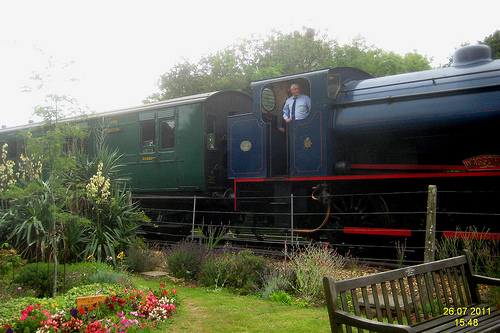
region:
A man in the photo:
[282, 74, 307, 121]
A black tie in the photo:
[290, 98, 300, 122]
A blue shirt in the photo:
[278, 94, 310, 121]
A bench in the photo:
[321, 264, 463, 323]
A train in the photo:
[336, 84, 496, 170]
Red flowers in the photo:
[21, 302, 38, 321]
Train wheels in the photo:
[316, 191, 404, 234]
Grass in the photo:
[203, 297, 267, 328]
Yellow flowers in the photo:
[87, 162, 112, 197]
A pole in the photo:
[424, 189, 440, 264]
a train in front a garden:
[5, 43, 497, 260]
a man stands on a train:
[221, 48, 346, 178]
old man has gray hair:
[274, 73, 315, 124]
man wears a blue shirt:
[276, 80, 313, 133]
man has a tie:
[279, 75, 313, 129]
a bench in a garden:
[313, 248, 498, 330]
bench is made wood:
[316, 242, 498, 331]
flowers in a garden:
[9, 275, 201, 331]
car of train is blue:
[224, 48, 498, 223]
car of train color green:
[3, 83, 233, 217]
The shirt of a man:
[277, 96, 314, 121]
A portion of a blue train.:
[226, 116, 271, 181]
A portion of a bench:
[326, 273, 431, 332]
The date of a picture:
[438, 302, 494, 326]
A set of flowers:
[121, 282, 176, 331]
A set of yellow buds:
[81, 158, 116, 210]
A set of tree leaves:
[258, 22, 322, 70]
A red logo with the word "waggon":
[455, 151, 499, 171]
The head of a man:
[287, 82, 307, 96]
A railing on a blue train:
[337, 66, 499, 98]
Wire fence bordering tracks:
[137, 194, 422, 264]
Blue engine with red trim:
[232, 61, 498, 238]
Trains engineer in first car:
[271, 80, 310, 120]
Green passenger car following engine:
[82, 88, 222, 198]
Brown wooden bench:
[311, 257, 496, 325]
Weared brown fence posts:
[417, 181, 442, 257]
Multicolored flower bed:
[12, 285, 184, 331]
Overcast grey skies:
[10, 21, 141, 97]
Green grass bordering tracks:
[206, 291, 318, 329]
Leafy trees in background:
[196, 40, 418, 70]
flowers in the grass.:
[138, 293, 158, 312]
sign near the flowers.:
[74, 290, 104, 312]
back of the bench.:
[380, 271, 418, 316]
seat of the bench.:
[445, 308, 488, 332]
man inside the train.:
[277, 81, 304, 127]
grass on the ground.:
[218, 299, 255, 322]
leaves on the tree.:
[280, 37, 312, 60]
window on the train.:
[157, 119, 172, 146]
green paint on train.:
[185, 120, 205, 162]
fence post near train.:
[425, 191, 439, 253]